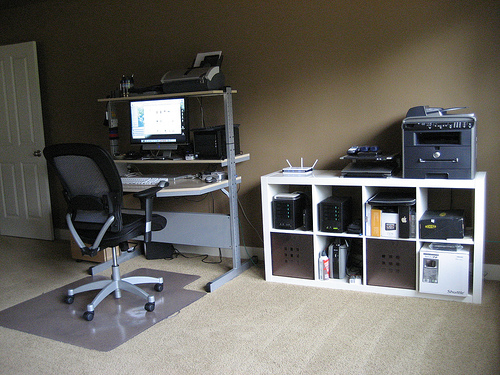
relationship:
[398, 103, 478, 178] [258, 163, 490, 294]
printer on shelf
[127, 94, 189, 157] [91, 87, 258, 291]
monitor on desk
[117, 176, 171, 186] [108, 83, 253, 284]
keyboard on desk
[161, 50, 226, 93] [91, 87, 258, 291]
printer on desk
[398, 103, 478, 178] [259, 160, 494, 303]
printer of shelf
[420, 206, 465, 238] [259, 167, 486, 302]
paper on desk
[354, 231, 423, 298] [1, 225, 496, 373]
box on floor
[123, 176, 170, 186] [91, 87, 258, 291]
keyboard on desk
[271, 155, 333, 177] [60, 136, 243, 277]
router on desk